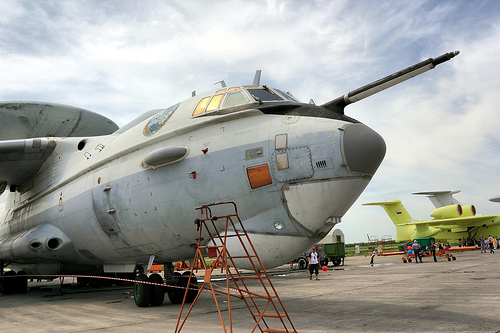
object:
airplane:
[364, 197, 500, 250]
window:
[222, 89, 250, 109]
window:
[192, 95, 208, 118]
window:
[206, 93, 226, 112]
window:
[248, 86, 296, 102]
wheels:
[165, 271, 200, 305]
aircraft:
[0, 48, 474, 292]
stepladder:
[180, 203, 294, 333]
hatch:
[248, 162, 270, 187]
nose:
[294, 111, 391, 188]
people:
[410, 238, 424, 264]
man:
[306, 244, 323, 281]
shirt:
[306, 251, 320, 264]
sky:
[2, 2, 500, 121]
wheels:
[132, 273, 164, 307]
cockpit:
[194, 83, 300, 115]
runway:
[4, 254, 494, 332]